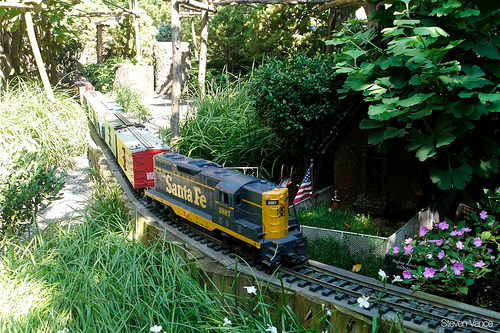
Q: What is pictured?
A: A model train.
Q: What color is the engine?
A: Grey and yellow.